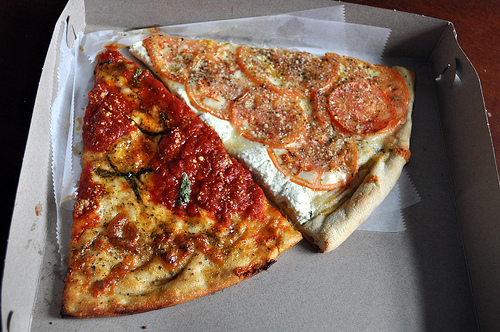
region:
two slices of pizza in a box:
[1, 3, 491, 330]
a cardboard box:
[288, 260, 485, 320]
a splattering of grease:
[29, 237, 58, 314]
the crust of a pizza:
[311, 211, 345, 251]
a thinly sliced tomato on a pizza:
[230, 87, 305, 143]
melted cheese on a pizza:
[107, 196, 158, 233]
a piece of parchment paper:
[265, 25, 371, 47]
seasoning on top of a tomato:
[283, 59, 328, 86]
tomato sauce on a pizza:
[191, 135, 225, 215]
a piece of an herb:
[180, 171, 190, 211]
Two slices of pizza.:
[53, 17, 423, 315]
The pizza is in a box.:
[1, 0, 496, 330]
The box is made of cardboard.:
[1, 1, 498, 330]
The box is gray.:
[0, 0, 499, 330]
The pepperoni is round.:
[144, 28, 412, 218]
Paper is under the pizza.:
[63, 17, 429, 277]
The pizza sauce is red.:
[166, 113, 239, 211]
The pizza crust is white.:
[308, 194, 389, 271]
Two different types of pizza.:
[71, 20, 411, 313]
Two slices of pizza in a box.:
[1, 0, 498, 330]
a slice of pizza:
[122, 180, 179, 240]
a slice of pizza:
[106, 116, 288, 318]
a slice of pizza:
[66, 136, 210, 289]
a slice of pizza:
[124, 182, 230, 307]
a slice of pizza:
[107, 168, 185, 304]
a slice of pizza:
[44, 3, 324, 315]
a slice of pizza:
[121, 51, 252, 257]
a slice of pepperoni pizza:
[51, 45, 300, 322]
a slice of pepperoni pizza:
[136, 21, 413, 253]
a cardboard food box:
[14, 0, 494, 328]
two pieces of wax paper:
[52, 11, 414, 264]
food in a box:
[0, 0, 495, 328]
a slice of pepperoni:
[228, 48, 340, 99]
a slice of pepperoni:
[328, 74, 394, 132]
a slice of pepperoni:
[265, 117, 362, 190]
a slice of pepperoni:
[228, 83, 306, 145]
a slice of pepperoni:
[188, 51, 248, 116]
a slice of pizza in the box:
[126, 25, 424, 260]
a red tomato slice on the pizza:
[259, 127, 374, 198]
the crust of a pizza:
[296, 63, 427, 253]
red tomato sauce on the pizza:
[78, 81, 138, 156]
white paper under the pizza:
[38, 2, 411, 289]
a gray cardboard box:
[1, 0, 499, 328]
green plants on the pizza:
[92, 151, 160, 206]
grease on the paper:
[208, 10, 319, 46]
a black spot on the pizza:
[239, 255, 285, 281]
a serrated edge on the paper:
[41, 21, 74, 283]